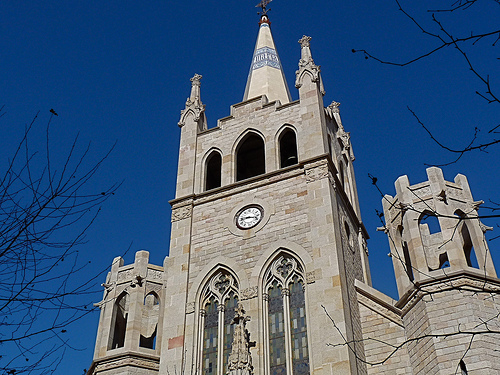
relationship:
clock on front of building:
[233, 204, 264, 230] [67, 31, 494, 373]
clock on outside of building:
[222, 197, 267, 237] [67, 31, 494, 373]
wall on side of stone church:
[185, 205, 225, 251] [80, 0, 500, 374]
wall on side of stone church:
[357, 284, 415, 374] [80, 0, 500, 374]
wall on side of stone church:
[176, 290, 238, 363] [80, 0, 500, 374]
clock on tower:
[233, 204, 264, 230] [157, 0, 376, 374]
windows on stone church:
[193, 240, 318, 372] [80, 0, 500, 374]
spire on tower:
[240, 13, 293, 113] [157, 0, 376, 374]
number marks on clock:
[239, 210, 269, 220] [234, 200, 266, 231]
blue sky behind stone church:
[6, 0, 497, 360] [80, 0, 500, 374]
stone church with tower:
[93, 3, 495, 373] [157, 0, 376, 374]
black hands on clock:
[237, 215, 258, 217] [229, 196, 266, 237]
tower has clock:
[89, 5, 495, 367] [231, 203, 266, 232]